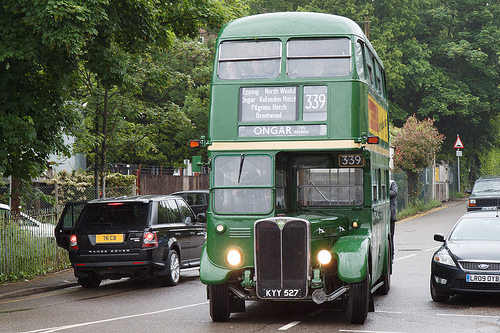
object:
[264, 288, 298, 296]
plate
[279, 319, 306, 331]
white line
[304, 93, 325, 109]
numbers 339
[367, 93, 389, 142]
yellow sign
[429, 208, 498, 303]
car is black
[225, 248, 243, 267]
headlight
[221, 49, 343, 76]
passengers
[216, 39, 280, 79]
bus's window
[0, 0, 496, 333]
traffic on a street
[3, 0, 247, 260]
tall green trees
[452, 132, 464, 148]
street sign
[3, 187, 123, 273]
metal fence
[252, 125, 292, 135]
word ongar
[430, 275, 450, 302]
wheel on a car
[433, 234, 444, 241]
mirror on a car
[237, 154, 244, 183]
windshield wiper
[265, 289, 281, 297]
letter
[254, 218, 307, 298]
grill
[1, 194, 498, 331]
pavement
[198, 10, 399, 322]
bus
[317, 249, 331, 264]
headlight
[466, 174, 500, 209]
vehicles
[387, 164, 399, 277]
person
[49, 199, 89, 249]
door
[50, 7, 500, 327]
traffic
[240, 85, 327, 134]
letters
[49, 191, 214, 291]
car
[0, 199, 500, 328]
road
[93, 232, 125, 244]
plate